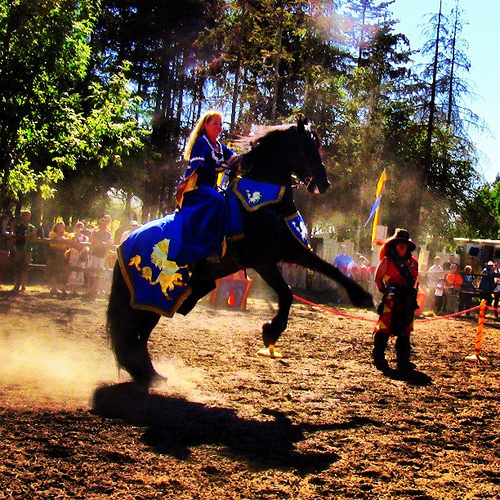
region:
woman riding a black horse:
[100, 87, 383, 410]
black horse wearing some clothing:
[96, 107, 384, 405]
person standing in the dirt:
[363, 227, 430, 372]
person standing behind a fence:
[4, 207, 46, 297]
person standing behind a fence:
[44, 216, 74, 300]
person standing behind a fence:
[80, 213, 112, 291]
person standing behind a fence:
[65, 217, 93, 289]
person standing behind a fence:
[330, 242, 351, 278]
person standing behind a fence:
[456, 262, 479, 319]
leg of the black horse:
[267, 223, 381, 317]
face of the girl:
[130, 58, 261, 170]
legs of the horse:
[77, 277, 227, 405]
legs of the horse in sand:
[86, 295, 263, 499]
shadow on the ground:
[179, 363, 291, 455]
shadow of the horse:
[185, 383, 295, 490]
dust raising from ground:
[13, 318, 113, 468]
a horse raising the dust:
[18, 295, 243, 497]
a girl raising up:
[123, 63, 370, 487]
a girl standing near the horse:
[341, 175, 496, 450]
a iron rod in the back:
[353, 153, 413, 272]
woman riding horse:
[91, 105, 381, 390]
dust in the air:
[21, 319, 62, 354]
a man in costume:
[370, 225, 427, 375]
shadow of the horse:
[84, 378, 386, 484]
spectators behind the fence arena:
[0, 206, 110, 300]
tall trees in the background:
[0, 4, 480, 111]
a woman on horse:
[166, 108, 239, 268]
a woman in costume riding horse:
[166, 108, 245, 275]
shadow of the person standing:
[375, 365, 436, 392]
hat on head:
[382, 225, 419, 250]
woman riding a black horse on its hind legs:
[105, 108, 379, 388]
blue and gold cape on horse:
[109, 178, 286, 319]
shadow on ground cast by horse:
[86, 376, 378, 478]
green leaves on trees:
[4, 3, 155, 213]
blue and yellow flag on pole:
[361, 167, 387, 276]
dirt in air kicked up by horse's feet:
[11, 307, 199, 407]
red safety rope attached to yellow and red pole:
[282, 287, 498, 359]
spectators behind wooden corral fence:
[5, 205, 143, 293]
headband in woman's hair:
[201, 112, 212, 124]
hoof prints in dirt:
[291, 347, 469, 494]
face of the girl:
[164, 90, 239, 145]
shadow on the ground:
[163, 410, 345, 489]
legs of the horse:
[233, 268, 343, 339]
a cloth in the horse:
[123, 210, 182, 292]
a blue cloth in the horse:
[116, 210, 210, 352]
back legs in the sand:
[100, 322, 240, 441]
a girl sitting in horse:
[128, 88, 297, 294]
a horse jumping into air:
[59, 105, 443, 498]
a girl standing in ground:
[351, 198, 450, 440]